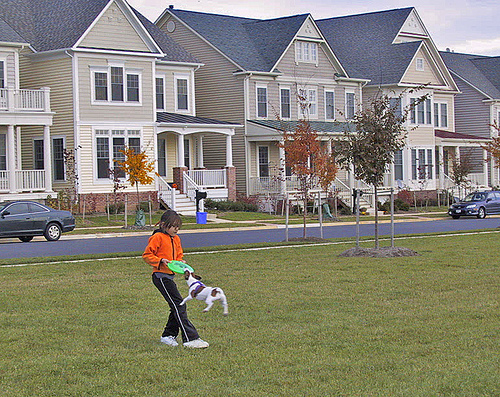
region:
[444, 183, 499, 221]
blue car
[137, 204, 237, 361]
a young girl playing frisbee with dog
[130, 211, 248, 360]
a girl holding a green frisbee which a dog is biting on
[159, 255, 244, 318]
a dog is biting on a green frisbee to hold itself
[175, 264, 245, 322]
white dog with brown patches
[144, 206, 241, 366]
a young girl with orange fleece jacket and black pants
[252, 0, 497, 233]
clean and nice looking exterior of houses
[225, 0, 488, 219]
houses with blue-colored roof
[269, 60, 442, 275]
short young trees with reddish leaves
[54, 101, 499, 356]
girl playing frisbee with dog in a park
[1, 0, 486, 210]
row of houses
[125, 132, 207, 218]
black mailbox in front of house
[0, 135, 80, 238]
dark vehicle parked near house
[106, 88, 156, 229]
small tree with yellow leaves in front of house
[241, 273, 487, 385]
well-trimmed grass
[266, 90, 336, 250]
tree with red leaves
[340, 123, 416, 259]
support poles on either side of tree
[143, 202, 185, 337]
girl holding a green Frisbee with both hands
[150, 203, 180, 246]
girl has dark hair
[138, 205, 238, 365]
dog is up above the ground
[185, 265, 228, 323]
A small brown and white dog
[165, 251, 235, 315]
A dog holding a green frisbee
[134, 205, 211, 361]
A child playing with a Frisbee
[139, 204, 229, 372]
A child playing with a dog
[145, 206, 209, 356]
A child wearing blue pants with a white strip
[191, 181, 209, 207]
A black mailbox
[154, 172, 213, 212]
White front steps on a house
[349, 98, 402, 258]
A young tree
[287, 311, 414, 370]
Grass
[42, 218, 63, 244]
The rear tire on a parked car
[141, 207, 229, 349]
a girl playing with a dog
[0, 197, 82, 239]
a dark car beside the road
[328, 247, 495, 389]
a green mowed lawn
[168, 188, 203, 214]
white front steps of a house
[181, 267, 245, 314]
a white and brown puppy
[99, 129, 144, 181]
large windows of a house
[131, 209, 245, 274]
a girl with an orange sweater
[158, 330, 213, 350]
white sport shoes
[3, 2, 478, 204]
two storey houses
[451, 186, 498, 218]
a dark car parked beside the road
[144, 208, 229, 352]
child playing with a dog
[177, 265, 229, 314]
brown and white dog playing with a child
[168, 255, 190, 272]
green Frisbee between dog and child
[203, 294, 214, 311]
left hind leg of dog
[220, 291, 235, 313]
right hind leg of dog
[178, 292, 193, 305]
left front leg of dog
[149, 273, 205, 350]
lower torso of child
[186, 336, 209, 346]
right foot of child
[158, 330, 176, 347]
left foot of child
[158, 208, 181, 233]
head of the child